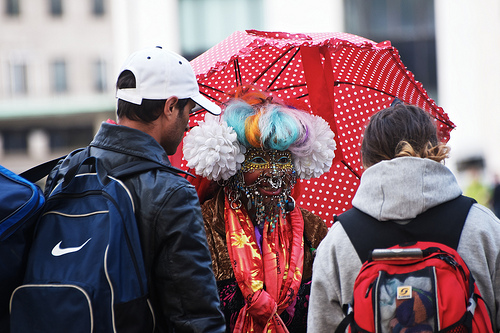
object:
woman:
[183, 93, 330, 332]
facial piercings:
[218, 145, 299, 236]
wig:
[180, 99, 339, 182]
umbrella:
[165, 28, 456, 231]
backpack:
[8, 147, 177, 332]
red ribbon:
[296, 41, 343, 163]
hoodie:
[305, 156, 499, 332]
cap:
[115, 44, 221, 116]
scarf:
[225, 187, 305, 332]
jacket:
[201, 198, 330, 332]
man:
[42, 47, 226, 333]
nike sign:
[51, 238, 93, 256]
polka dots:
[343, 60, 370, 73]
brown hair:
[116, 69, 197, 121]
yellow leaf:
[229, 228, 264, 262]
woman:
[308, 103, 500, 332]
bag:
[333, 196, 494, 331]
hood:
[351, 155, 465, 221]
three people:
[0, 43, 500, 331]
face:
[229, 144, 296, 216]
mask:
[224, 145, 296, 228]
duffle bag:
[1, 162, 48, 240]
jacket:
[45, 123, 226, 332]